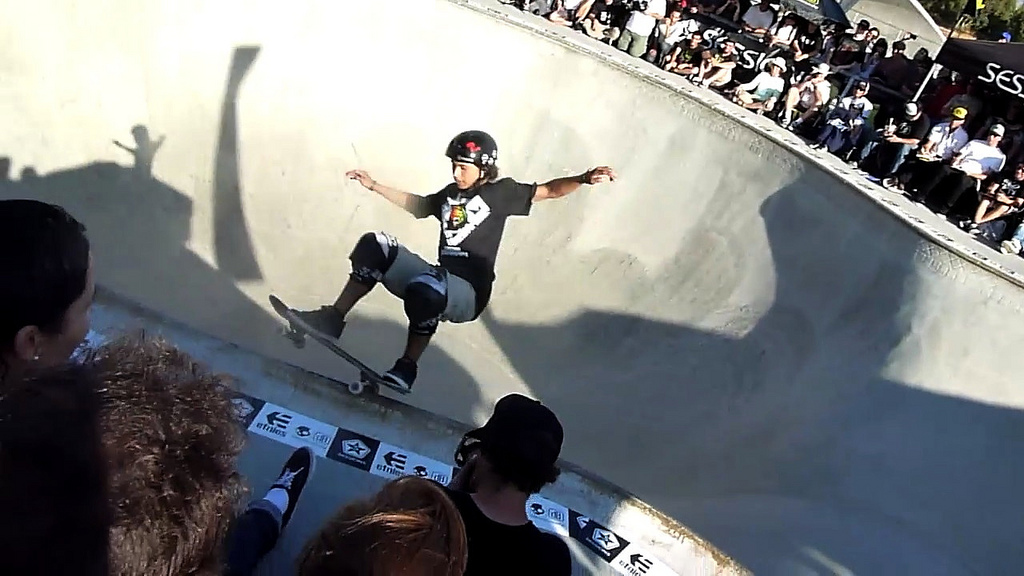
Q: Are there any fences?
A: No, there are no fences.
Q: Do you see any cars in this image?
A: No, there are no cars.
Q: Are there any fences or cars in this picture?
A: No, there are no cars or fences.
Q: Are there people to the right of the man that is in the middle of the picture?
A: Yes, there is a person to the right of the man.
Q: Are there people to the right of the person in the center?
A: Yes, there is a person to the right of the man.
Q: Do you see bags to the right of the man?
A: No, there is a person to the right of the man.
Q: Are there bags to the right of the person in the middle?
A: No, there is a person to the right of the man.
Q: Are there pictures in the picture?
A: No, there are no pictures.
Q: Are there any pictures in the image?
A: No, there are no pictures.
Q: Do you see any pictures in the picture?
A: No, there are no pictures.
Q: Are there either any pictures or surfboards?
A: No, there are no pictures or surfboards.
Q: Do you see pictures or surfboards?
A: No, there are no pictures or surfboards.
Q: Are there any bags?
A: No, there are no bags.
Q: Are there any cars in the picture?
A: No, there are no cars.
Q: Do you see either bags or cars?
A: No, there are no cars or bags.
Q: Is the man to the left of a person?
A: Yes, the man is to the left of a person.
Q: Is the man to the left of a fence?
A: No, the man is to the left of a person.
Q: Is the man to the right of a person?
A: No, the man is to the left of a person.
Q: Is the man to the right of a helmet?
A: No, the man is to the right of a person.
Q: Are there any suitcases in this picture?
A: No, there are no suitcases.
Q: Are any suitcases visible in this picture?
A: No, there are no suitcases.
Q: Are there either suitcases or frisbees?
A: No, there are no suitcases or frisbees.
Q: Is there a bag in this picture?
A: No, there are no bags.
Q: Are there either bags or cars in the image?
A: No, there are no bags or cars.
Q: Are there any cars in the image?
A: No, there are no cars.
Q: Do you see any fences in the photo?
A: No, there are no fences.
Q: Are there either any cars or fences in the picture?
A: No, there are no fences or cars.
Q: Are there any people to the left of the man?
A: Yes, there is a person to the left of the man.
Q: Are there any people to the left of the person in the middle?
A: Yes, there is a person to the left of the man.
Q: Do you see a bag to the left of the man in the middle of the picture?
A: No, there is a person to the left of the man.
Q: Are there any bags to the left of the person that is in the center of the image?
A: No, there is a person to the left of the man.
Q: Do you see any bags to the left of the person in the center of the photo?
A: No, there is a person to the left of the man.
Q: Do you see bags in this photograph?
A: No, there are no bags.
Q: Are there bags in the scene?
A: No, there are no bags.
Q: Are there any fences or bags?
A: No, there are no bags or fences.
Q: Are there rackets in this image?
A: No, there are no rackets.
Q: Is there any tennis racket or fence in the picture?
A: No, there are no rackets or fences.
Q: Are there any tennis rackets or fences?
A: No, there are no tennis rackets or fences.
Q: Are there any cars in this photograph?
A: No, there are no cars.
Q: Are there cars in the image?
A: No, there are no cars.